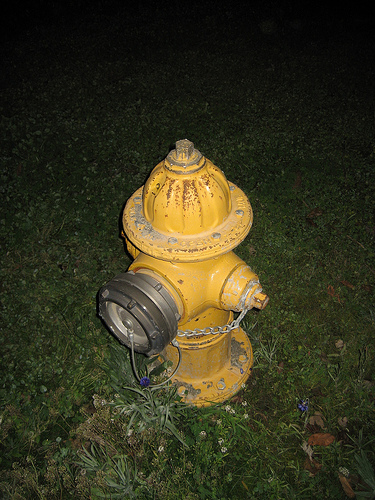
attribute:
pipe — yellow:
[121, 136, 270, 406]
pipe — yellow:
[117, 146, 260, 407]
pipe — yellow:
[121, 150, 266, 414]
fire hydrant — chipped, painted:
[129, 171, 255, 369]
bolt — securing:
[197, 369, 244, 396]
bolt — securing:
[192, 219, 231, 247]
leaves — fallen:
[288, 408, 359, 491]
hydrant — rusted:
[131, 264, 278, 409]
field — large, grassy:
[206, 53, 372, 301]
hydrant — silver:
[86, 276, 161, 344]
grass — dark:
[19, 123, 97, 241]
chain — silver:
[158, 292, 267, 362]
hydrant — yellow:
[95, 145, 289, 381]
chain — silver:
[185, 293, 293, 374]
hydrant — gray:
[101, 182, 268, 390]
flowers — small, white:
[181, 388, 273, 444]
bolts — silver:
[215, 195, 253, 225]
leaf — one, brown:
[294, 430, 342, 449]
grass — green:
[315, 445, 345, 461]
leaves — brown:
[293, 402, 368, 498]